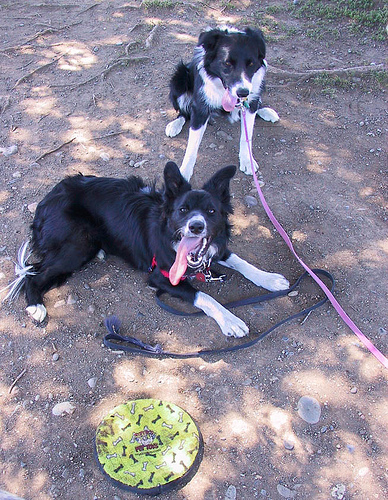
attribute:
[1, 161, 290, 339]
dog — black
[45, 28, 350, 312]
dogs — black and white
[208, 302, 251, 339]
paw — white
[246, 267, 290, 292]
paw — white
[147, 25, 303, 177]
dog — sitting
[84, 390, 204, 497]
dog toy — yellow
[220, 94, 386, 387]
leash — dark blue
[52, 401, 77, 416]
rock — large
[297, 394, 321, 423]
rock — large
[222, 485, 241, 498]
rock — large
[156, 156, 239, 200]
ears — pointed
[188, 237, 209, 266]
teeth — white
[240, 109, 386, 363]
leash — bright pink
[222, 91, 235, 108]
tongue — long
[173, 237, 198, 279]
tongue — long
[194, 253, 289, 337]
paws — white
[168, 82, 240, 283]
toungues — hanging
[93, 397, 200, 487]
pet toy — round